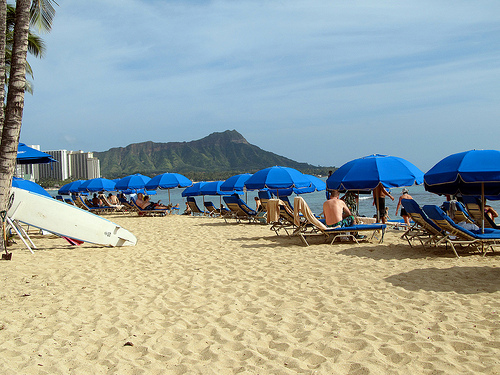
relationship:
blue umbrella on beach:
[243, 165, 311, 189] [212, 218, 317, 345]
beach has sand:
[0, 142, 495, 374] [120, 248, 412, 369]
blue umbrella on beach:
[145, 172, 194, 188] [3, 205, 497, 373]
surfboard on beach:
[10, 187, 145, 253] [4, 225, 497, 370]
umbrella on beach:
[182, 181, 212, 216] [3, 177, 495, 373]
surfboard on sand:
[10, 187, 138, 247] [0, 209, 498, 373]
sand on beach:
[0, 209, 498, 373] [3, 177, 495, 373]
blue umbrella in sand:
[421, 146, 499, 258] [0, 209, 498, 373]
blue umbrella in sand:
[323, 150, 428, 231] [0, 209, 498, 373]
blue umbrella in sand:
[243, 164, 314, 224] [0, 209, 498, 373]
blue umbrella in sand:
[219, 170, 254, 222] [0, 209, 498, 373]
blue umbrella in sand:
[194, 178, 246, 217] [0, 209, 498, 373]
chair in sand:
[216, 187, 258, 231] [234, 263, 434, 350]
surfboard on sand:
[10, 187, 138, 247] [132, 199, 183, 286]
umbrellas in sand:
[58, 149, 496, 197] [0, 209, 498, 373]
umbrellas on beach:
[58, 149, 496, 197] [3, 205, 497, 373]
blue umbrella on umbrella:
[323, 154, 428, 189] [427, 142, 497, 204]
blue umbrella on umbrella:
[323, 154, 428, 189] [244, 160, 309, 187]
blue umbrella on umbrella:
[323, 154, 428, 189] [271, 173, 333, 194]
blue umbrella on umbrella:
[323, 154, 428, 189] [223, 172, 258, 192]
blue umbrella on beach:
[323, 154, 428, 189] [3, 177, 495, 373]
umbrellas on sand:
[58, 149, 496, 197] [0, 209, 498, 373]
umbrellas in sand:
[58, 149, 496, 197] [182, 269, 326, 321]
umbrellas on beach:
[4, 133, 496, 257] [3, 177, 495, 373]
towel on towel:
[290, 195, 335, 235] [260, 195, 294, 225]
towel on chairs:
[290, 195, 335, 235] [291, 197, 388, 244]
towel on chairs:
[290, 195, 335, 235] [262, 197, 329, 239]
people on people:
[321, 188, 352, 227] [483, 200, 499, 221]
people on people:
[321, 188, 352, 227] [137, 193, 170, 211]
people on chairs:
[321, 188, 352, 227] [291, 197, 388, 244]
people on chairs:
[321, 188, 352, 227] [463, 195, 499, 232]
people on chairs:
[321, 188, 352, 227] [126, 196, 168, 216]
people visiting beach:
[71, 175, 485, 235] [71, 189, 465, 314]